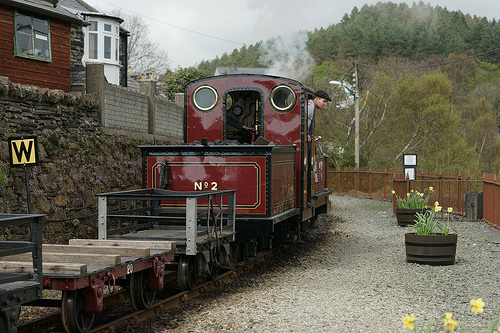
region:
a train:
[198, 25, 310, 322]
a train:
[196, 70, 268, 200]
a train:
[174, 131, 296, 312]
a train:
[237, 69, 349, 329]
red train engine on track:
[110, 57, 365, 246]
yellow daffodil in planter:
[384, 304, 419, 326]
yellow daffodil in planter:
[433, 310, 456, 330]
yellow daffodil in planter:
[454, 292, 480, 317]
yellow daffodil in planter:
[446, 205, 453, 214]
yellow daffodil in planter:
[433, 206, 443, 216]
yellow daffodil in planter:
[432, 200, 439, 206]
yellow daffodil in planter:
[424, 181, 436, 188]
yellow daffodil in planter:
[416, 189, 423, 198]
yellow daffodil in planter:
[387, 186, 397, 196]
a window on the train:
[188, 80, 223, 115]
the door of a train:
[220, 85, 267, 145]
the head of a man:
[309, 85, 334, 110]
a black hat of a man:
[313, 85, 335, 103]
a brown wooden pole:
[346, 56, 368, 167]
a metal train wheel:
[124, 262, 166, 309]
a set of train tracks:
[3, 205, 326, 332]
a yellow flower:
[399, 305, 422, 332]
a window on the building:
[11, 10, 56, 65]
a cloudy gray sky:
[81, 0, 498, 86]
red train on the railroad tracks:
[138, 47, 308, 279]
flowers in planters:
[381, 183, 474, 276]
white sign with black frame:
[394, 147, 419, 179]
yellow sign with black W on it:
[9, 136, 40, 168]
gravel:
[296, 268, 387, 323]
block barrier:
[83, 71, 181, 140]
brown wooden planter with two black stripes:
[403, 232, 463, 265]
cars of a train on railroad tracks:
[2, 190, 240, 331]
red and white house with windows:
[1, 0, 127, 93]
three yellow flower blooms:
[393, 292, 491, 332]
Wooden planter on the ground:
[406, 217, 461, 268]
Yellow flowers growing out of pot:
[396, 290, 491, 326]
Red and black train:
[165, 65, 350, 260]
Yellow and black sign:
[5, 130, 50, 170]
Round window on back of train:
[185, 80, 220, 117]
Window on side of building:
[9, 10, 59, 70]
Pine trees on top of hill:
[323, 2, 498, 69]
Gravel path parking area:
[325, 243, 401, 326]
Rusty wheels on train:
[127, 242, 170, 326]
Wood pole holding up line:
[340, 54, 367, 170]